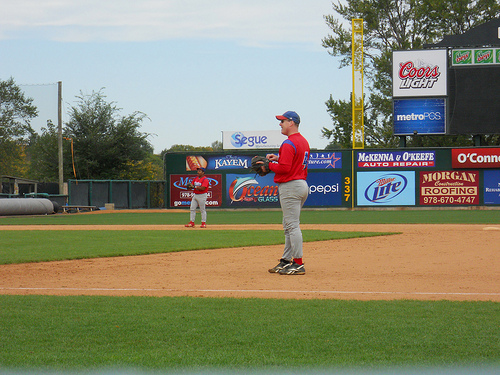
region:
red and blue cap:
[267, 103, 304, 128]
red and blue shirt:
[282, 124, 317, 180]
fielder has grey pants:
[262, 181, 318, 276]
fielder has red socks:
[274, 242, 316, 267]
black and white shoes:
[250, 242, 303, 293]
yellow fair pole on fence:
[322, 17, 374, 161]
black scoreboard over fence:
[457, 19, 499, 130]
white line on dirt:
[325, 238, 417, 317]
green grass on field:
[341, 327, 412, 374]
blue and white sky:
[143, 22, 230, 116]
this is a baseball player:
[242, 97, 316, 291]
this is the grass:
[204, 312, 326, 342]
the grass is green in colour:
[235, 328, 333, 348]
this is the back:
[292, 145, 307, 177]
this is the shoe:
[282, 262, 307, 274]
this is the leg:
[285, 190, 303, 261]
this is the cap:
[277, 111, 299, 118]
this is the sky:
[170, 47, 284, 99]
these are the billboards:
[394, 52, 447, 134]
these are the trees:
[77, 129, 160, 175]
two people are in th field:
[118, 127, 413, 347]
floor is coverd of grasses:
[243, 326, 315, 366]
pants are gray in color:
[274, 180, 323, 305]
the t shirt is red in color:
[269, 134, 323, 175]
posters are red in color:
[393, 62, 451, 131]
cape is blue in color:
[271, 109, 307, 141]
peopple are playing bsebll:
[190, 143, 390, 305]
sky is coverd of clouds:
[142, 24, 224, 74]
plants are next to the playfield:
[48, 117, 156, 161]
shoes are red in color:
[174, 208, 223, 240]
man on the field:
[257, 110, 307, 278]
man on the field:
[174, 168, 212, 230]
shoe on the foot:
[282, 260, 302, 277]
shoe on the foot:
[262, 259, 282, 280]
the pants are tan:
[284, 236, 307, 248]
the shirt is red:
[279, 162, 300, 175]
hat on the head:
[274, 109, 304, 121]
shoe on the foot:
[195, 216, 207, 231]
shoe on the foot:
[182, 220, 192, 230]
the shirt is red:
[200, 181, 210, 188]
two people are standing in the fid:
[161, 123, 406, 318]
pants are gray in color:
[278, 179, 312, 256]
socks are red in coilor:
[288, 254, 321, 269]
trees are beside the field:
[71, 94, 136, 183]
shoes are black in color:
[260, 260, 327, 287]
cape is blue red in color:
[275, 95, 303, 167]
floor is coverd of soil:
[388, 258, 460, 297]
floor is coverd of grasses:
[311, 329, 411, 373]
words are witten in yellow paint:
[343, 174, 362, 204]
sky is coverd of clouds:
[234, 30, 306, 87]